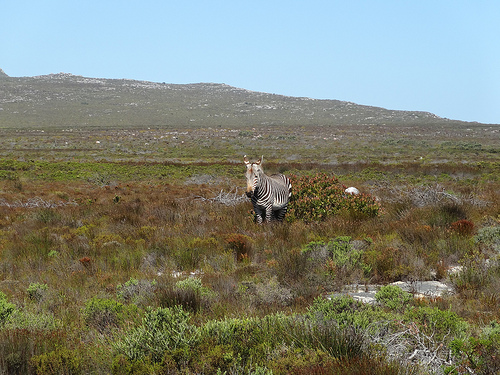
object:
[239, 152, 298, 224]
zebra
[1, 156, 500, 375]
field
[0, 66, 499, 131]
mountain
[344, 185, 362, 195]
object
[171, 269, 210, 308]
plant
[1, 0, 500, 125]
sky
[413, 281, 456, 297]
rock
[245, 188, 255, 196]
nose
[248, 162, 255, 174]
mark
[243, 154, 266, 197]
zebra's head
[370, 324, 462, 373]
sticks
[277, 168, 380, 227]
bush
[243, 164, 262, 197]
face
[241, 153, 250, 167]
ear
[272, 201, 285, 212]
underbelly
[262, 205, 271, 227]
leg